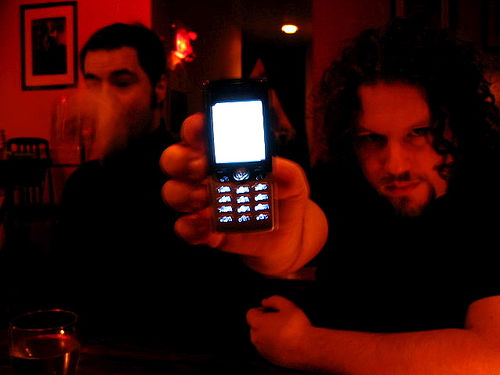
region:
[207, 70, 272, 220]
this is a phone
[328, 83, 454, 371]
this is a man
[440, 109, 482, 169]
the hair is black in color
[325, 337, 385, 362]
the man is light skinned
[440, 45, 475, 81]
this is the hair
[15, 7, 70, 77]
this is a picture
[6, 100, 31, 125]
this is the wall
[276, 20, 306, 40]
this is a light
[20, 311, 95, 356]
this is a glass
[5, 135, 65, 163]
this is a chair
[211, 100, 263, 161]
smartphone screen pure white because of reflected light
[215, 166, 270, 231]
backlit illuminated smartphone buttons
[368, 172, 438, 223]
well groomed black facial hair in goatee style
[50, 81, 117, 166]
glass filled with alcoholic beverage being quaffed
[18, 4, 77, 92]
black framed photograph hanging on wall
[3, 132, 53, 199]
wooden chair back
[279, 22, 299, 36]
illuminated round track light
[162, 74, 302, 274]
hand grasping smartphone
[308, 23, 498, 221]
long haired male face staring at camera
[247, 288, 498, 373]
bare arm colored red due to oversaturation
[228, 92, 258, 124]
part of a screen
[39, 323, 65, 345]
edge of a glass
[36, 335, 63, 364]
part of a glass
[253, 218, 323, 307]
part of a phone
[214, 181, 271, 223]
The number pad on the phone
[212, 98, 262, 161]
The display of the cell phone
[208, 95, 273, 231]
A rectangular cell phone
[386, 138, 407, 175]
The nose of the man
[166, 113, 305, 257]
A cell phone in the man's right hand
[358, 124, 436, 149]
The eyes of the man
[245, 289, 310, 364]
The left hand of the man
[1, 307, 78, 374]
A glass full of a liquid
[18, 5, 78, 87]
A picture frame on the wall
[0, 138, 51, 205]
A chair by the white wall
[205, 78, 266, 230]
this is a cell phone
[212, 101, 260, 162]
the phone is on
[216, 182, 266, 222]
the buttons are on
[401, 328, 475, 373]
this is a hand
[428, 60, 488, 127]
this is the hair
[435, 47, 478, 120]
the hair is long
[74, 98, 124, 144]
the man is smoking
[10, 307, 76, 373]
this is a glass of water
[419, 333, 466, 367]
the man is light skinned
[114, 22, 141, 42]
the hair is black in color